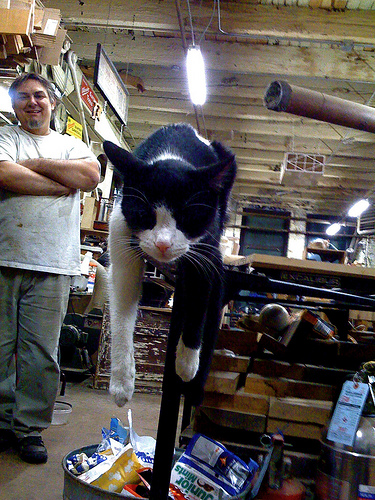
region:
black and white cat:
[100, 118, 237, 415]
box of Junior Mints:
[166, 459, 230, 498]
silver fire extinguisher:
[314, 351, 371, 498]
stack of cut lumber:
[208, 355, 318, 440]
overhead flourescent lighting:
[184, 33, 218, 116]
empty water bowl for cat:
[44, 393, 77, 424]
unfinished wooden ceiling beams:
[215, 12, 369, 89]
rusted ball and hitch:
[245, 298, 316, 358]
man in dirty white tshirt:
[2, 77, 104, 288]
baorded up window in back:
[235, 206, 299, 252]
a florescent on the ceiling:
[173, 38, 209, 115]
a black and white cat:
[93, 121, 239, 410]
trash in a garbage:
[70, 416, 263, 495]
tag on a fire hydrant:
[323, 365, 364, 454]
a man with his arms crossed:
[0, 62, 80, 465]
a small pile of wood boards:
[218, 358, 312, 427]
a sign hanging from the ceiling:
[92, 36, 140, 117]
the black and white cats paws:
[101, 339, 208, 409]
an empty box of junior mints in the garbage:
[168, 461, 238, 499]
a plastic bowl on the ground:
[51, 402, 79, 427]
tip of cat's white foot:
[100, 373, 153, 407]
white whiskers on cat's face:
[92, 230, 156, 271]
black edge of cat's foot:
[178, 336, 224, 351]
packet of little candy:
[162, 455, 242, 498]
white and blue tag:
[320, 369, 374, 463]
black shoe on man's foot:
[9, 419, 66, 459]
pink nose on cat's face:
[151, 234, 198, 270]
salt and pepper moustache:
[13, 110, 67, 138]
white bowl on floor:
[52, 394, 82, 425]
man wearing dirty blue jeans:
[3, 271, 96, 441]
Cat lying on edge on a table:
[91, 99, 245, 427]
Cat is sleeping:
[84, 111, 241, 415]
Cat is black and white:
[87, 106, 243, 417]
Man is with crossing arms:
[5, 71, 106, 472]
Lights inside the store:
[317, 189, 374, 245]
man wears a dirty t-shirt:
[1, 62, 97, 471]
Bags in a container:
[54, 410, 284, 499]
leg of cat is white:
[98, 214, 147, 404]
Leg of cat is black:
[176, 251, 224, 347]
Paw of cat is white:
[166, 344, 209, 389]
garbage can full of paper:
[57, 439, 271, 496]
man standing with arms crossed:
[0, 64, 107, 308]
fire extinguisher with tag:
[315, 357, 372, 493]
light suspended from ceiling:
[180, 36, 221, 114]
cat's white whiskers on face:
[181, 238, 228, 285]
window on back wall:
[236, 198, 292, 265]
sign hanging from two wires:
[89, 38, 139, 130]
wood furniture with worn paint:
[87, 303, 181, 398]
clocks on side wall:
[46, 95, 73, 138]